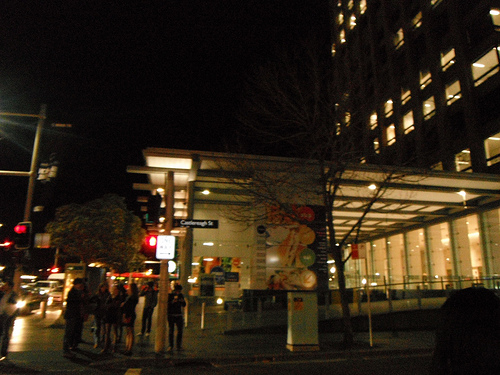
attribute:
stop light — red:
[143, 233, 159, 248]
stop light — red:
[12, 222, 27, 239]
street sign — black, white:
[169, 217, 220, 230]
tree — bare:
[208, 29, 443, 348]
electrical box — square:
[285, 287, 323, 352]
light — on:
[464, 231, 483, 243]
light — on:
[438, 233, 450, 249]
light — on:
[416, 231, 424, 239]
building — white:
[310, 2, 499, 319]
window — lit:
[381, 121, 398, 150]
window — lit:
[401, 113, 414, 132]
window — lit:
[417, 94, 438, 123]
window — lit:
[439, 76, 465, 111]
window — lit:
[462, 44, 499, 86]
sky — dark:
[1, 3, 340, 259]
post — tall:
[155, 167, 168, 359]